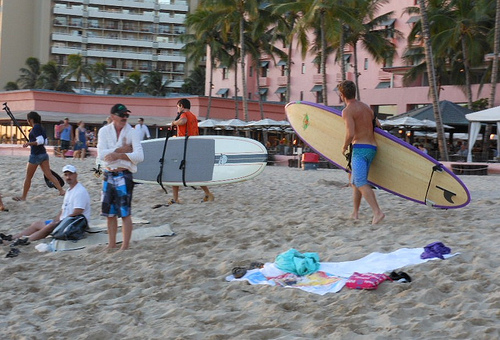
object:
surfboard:
[133, 136, 268, 185]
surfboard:
[283, 101, 471, 209]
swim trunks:
[350, 143, 377, 188]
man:
[164, 98, 214, 205]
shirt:
[176, 112, 200, 137]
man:
[58, 116, 72, 158]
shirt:
[59, 124, 72, 142]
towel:
[260, 249, 320, 287]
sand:
[0, 155, 499, 340]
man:
[0, 164, 92, 245]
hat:
[62, 164, 77, 175]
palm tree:
[405, 3, 489, 162]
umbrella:
[379, 116, 453, 129]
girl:
[12, 111, 65, 201]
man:
[337, 80, 385, 224]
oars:
[2, 101, 64, 189]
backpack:
[50, 213, 89, 241]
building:
[204, 0, 499, 136]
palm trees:
[180, 1, 241, 120]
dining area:
[196, 99, 497, 161]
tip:
[282, 99, 299, 123]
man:
[96, 103, 144, 255]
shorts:
[100, 167, 134, 218]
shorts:
[28, 147, 49, 166]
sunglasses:
[112, 110, 129, 118]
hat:
[110, 104, 132, 114]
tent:
[465, 104, 500, 163]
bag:
[346, 271, 389, 290]